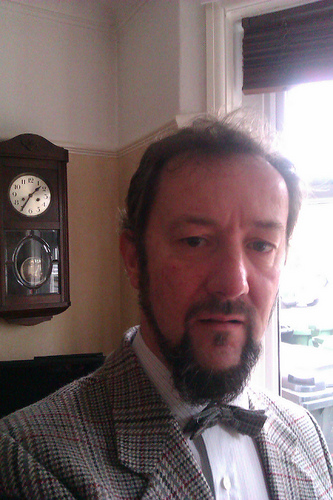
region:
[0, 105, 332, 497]
a white man posing for camera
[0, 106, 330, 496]
a man wearing a gray and red suit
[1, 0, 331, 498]
a scene indoors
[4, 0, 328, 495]
a scene in a house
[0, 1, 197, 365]
a white and tan wall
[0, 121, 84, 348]
a brown clock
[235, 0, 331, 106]
a brown curtains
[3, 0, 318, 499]
a scene happening during the day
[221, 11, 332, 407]
the sun shinning through a window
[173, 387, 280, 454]
a bow tie on the men's neck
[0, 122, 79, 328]
wooden clock on the wall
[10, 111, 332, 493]
guy with short hair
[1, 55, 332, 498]
guy with side burns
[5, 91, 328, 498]
guy with a mustache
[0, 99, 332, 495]
guy with a beard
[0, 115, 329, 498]
guy wearing a bow tie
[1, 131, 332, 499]
guy wearing a collared shirt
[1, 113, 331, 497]
guy wearing a suit jacket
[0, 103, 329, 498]
guy near a clock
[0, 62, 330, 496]
guy near a window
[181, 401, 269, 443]
drooping bowtie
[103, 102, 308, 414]
man looking concerned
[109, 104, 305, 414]
balding man with a beard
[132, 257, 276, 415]
well groomed beard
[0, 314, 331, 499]
plaid jacket worn by the man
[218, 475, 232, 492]
white button on a shirt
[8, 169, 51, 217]
face of the clock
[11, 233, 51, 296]
pendulum inside of the clock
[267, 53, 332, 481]
window showing bright sunlight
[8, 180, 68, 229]
Silver face on clock.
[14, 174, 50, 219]
Clock has black hands.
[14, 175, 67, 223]
Clock has black numbers.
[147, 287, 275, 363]
Man has dark facial hair.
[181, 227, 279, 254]
Man has brown eyes.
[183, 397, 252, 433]
Man is wearing bow tie.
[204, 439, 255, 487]
Man is wearing button down shirt.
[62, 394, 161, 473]
Man is wearing multi colored jacket.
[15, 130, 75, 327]
Wood clock attached to wall.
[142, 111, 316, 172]
Man has short brown hair.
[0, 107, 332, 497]
this is a person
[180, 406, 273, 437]
this is a bow tie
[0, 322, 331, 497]
the man is wearing a checked coat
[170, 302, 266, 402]
the man has a beard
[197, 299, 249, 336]
the mouth of a man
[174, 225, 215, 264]
the eye of a man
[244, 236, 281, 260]
the eye of a man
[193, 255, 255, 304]
the nose of a man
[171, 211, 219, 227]
the eye lashes of a man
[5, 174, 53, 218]
this is a clock